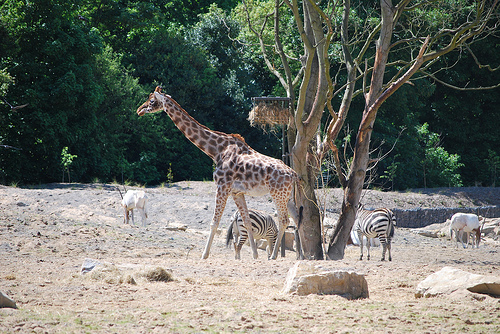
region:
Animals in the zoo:
[115, 65, 490, 279]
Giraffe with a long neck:
[148, 80, 234, 165]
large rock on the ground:
[273, 242, 383, 297]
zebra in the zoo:
[343, 194, 396, 257]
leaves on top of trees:
[60, 10, 282, 87]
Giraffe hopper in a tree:
[250, 83, 293, 135]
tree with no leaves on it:
[318, 48, 382, 263]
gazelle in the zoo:
[103, 177, 164, 226]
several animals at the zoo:
[97, 53, 425, 268]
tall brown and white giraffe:
[127, 78, 327, 272]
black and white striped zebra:
[221, 203, 291, 264]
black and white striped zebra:
[345, 186, 399, 270]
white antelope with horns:
[111, 178, 151, 230]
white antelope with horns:
[442, 201, 487, 246]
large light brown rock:
[270, 259, 378, 311]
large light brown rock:
[411, 262, 498, 310]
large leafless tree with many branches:
[228, 1, 490, 263]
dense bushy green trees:
[4, 5, 498, 205]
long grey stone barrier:
[338, 201, 498, 241]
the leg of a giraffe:
[194, 182, 228, 261]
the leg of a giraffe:
[231, 196, 261, 262]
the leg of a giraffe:
[270, 193, 289, 264]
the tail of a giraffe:
[293, 175, 310, 235]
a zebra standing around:
[225, 204, 290, 261]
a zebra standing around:
[345, 194, 399, 264]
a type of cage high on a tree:
[248, 95, 300, 129]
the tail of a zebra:
[225, 212, 237, 247]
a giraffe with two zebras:
[135, 79, 405, 269]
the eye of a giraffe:
[148, 97, 156, 104]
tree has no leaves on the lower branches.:
[240, 12, 495, 257]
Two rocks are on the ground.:
[286, 260, 496, 317]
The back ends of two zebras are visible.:
[230, 201, 397, 265]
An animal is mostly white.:
[118, 182, 156, 222]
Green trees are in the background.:
[1, 0, 497, 183]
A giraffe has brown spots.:
[137, 82, 303, 262]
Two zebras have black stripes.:
[225, 204, 404, 266]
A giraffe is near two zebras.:
[138, 85, 397, 260]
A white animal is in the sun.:
[446, 210, 493, 250]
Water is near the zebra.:
[365, 202, 498, 229]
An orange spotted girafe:
[133, 84, 305, 261]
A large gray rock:
[281, 261, 371, 303]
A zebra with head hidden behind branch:
[355, 201, 396, 259]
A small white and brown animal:
[115, 184, 149, 224]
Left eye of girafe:
[148, 99, 155, 104]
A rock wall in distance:
[324, 206, 499, 233]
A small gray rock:
[80, 256, 103, 274]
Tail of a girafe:
[292, 171, 304, 233]